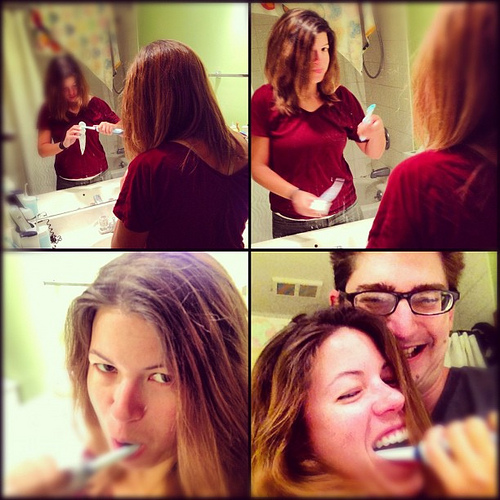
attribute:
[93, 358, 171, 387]
eyes — brown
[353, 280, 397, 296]
eyebrow — thick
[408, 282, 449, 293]
eyebrow — thick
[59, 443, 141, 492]
brush — white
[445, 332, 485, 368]
shower curtain — white, bunched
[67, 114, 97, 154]
toothpaste — tube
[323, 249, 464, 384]
man — smiling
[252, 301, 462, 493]
woman — smiling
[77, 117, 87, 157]
tube — white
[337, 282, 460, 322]
glasses — black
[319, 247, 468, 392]
man — smiling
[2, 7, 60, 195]
shower curtain — white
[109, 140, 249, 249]
shirt — red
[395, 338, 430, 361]
smile — big